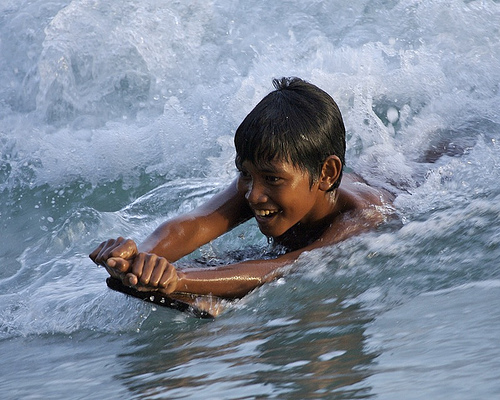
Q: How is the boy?
A: Wet.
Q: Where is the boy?
A: In the water.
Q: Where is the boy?
A: In the ocean.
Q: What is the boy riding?
A: A wave.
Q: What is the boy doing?
A: Holding on to something.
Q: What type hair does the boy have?
A: Short hair.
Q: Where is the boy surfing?
A: In the ocean.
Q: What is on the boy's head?
A: Wet black hair.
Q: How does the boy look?
A: Very happy.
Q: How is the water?
A: Very rough.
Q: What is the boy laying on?
A: A surfboard.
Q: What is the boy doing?
A: Surfing.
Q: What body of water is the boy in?
A: The ocean.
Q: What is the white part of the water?
A: The waves.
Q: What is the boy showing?
A: His teeth.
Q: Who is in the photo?
A: A boy.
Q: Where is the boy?
A: In the ocean.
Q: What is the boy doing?
A: Surfing.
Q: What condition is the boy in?
A: Wet.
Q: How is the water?
A: Foamy.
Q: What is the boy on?
A: A board.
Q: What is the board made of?
A: Wood.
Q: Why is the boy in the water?
A: Recreation.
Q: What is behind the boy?
A: Wave.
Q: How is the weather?
A: Warm.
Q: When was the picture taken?
A: Day time.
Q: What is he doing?
A: Body surfing.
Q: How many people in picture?
A: One.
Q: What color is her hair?
A: Black.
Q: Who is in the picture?
A: A boy.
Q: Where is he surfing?
A: The water.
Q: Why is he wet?
A: Because he's in water.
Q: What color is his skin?
A: Brown.